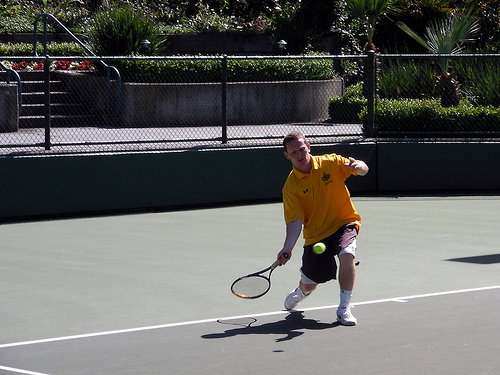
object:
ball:
[312, 242, 326, 255]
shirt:
[282, 153, 362, 247]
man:
[276, 130, 369, 326]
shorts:
[297, 223, 360, 284]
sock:
[337, 289, 353, 310]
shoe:
[335, 305, 358, 326]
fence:
[0, 53, 499, 160]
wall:
[0, 60, 345, 133]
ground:
[0, 0, 499, 371]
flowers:
[11, 60, 92, 71]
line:
[0, 284, 500, 348]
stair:
[0, 70, 99, 129]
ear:
[307, 143, 311, 152]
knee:
[339, 247, 356, 263]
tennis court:
[0, 194, 499, 373]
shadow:
[200, 309, 356, 352]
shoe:
[283, 286, 311, 310]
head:
[282, 130, 312, 167]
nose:
[296, 150, 303, 158]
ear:
[283, 151, 290, 160]